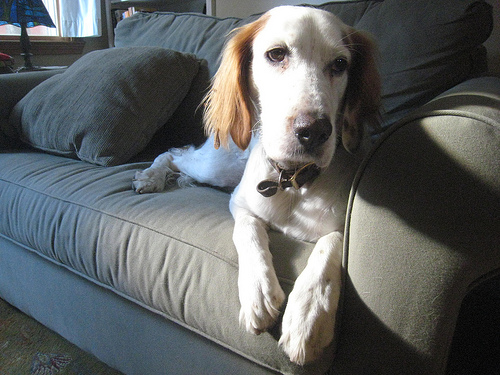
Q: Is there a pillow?
A: Yes, there is a pillow.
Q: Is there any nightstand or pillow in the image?
A: Yes, there is a pillow.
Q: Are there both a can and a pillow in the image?
A: No, there is a pillow but no cans.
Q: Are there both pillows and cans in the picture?
A: No, there is a pillow but no cans.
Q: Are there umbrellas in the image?
A: No, there are no umbrellas.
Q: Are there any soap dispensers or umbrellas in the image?
A: No, there are no umbrellas or soap dispensers.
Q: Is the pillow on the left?
A: Yes, the pillow is on the left of the image.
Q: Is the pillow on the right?
A: No, the pillow is on the left of the image.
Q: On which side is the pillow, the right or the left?
A: The pillow is on the left of the image.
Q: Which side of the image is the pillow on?
A: The pillow is on the left of the image.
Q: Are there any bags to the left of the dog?
A: No, there is a pillow to the left of the dog.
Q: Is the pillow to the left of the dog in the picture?
A: Yes, the pillow is to the left of the dog.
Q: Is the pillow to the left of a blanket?
A: No, the pillow is to the left of the dog.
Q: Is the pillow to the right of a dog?
A: No, the pillow is to the left of a dog.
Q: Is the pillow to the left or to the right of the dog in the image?
A: The pillow is to the left of the dog.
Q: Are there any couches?
A: Yes, there is a couch.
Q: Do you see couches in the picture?
A: Yes, there is a couch.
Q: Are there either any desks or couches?
A: Yes, there is a couch.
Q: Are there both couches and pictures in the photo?
A: No, there is a couch but no pictures.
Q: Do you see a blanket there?
A: No, there are no blankets.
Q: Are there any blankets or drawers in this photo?
A: No, there are no blankets or drawers.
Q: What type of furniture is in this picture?
A: The furniture is a couch.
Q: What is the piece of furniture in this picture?
A: The piece of furniture is a couch.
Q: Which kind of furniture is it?
A: The piece of furniture is a couch.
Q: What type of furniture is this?
A: This is a couch.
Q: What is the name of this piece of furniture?
A: This is a couch.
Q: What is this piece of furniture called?
A: This is a couch.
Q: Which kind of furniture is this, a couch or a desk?
A: This is a couch.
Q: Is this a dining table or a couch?
A: This is a couch.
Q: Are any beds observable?
A: No, there are no beds.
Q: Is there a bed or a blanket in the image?
A: No, there are no beds or blankets.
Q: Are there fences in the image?
A: No, there are no fences.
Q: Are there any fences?
A: No, there are no fences.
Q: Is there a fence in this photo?
A: No, there are no fences.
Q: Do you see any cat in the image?
A: No, there are no cats.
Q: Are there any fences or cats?
A: No, there are no cats or fences.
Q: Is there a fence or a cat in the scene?
A: No, there are no cats or fences.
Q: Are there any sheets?
A: No, there are no sheets.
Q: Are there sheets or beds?
A: No, there are no sheets or beds.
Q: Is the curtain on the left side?
A: Yes, the curtain is on the left of the image.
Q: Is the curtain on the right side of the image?
A: No, the curtain is on the left of the image.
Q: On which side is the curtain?
A: The curtain is on the left of the image.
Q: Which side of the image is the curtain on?
A: The curtain is on the left of the image.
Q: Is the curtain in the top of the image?
A: Yes, the curtain is in the top of the image.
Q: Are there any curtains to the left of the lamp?
A: No, the curtain is to the right of the lamp.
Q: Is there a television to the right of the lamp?
A: No, there is a curtain to the right of the lamp.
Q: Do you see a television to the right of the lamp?
A: No, there is a curtain to the right of the lamp.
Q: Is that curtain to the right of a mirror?
A: No, the curtain is to the right of the lamp.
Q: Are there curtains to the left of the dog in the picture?
A: Yes, there is a curtain to the left of the dog.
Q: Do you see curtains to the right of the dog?
A: No, the curtain is to the left of the dog.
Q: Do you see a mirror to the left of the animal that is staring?
A: No, there is a curtain to the left of the dog.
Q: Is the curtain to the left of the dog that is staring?
A: Yes, the curtain is to the left of the dog.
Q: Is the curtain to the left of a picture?
A: No, the curtain is to the left of the dog.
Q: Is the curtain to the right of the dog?
A: No, the curtain is to the left of the dog.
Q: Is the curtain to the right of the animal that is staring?
A: No, the curtain is to the left of the dog.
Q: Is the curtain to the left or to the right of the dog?
A: The curtain is to the left of the dog.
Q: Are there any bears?
A: No, there are no bears.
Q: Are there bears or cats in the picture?
A: No, there are no bears or cats.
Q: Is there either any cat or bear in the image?
A: No, there are no bears or cats.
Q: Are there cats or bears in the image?
A: No, there are no bears or cats.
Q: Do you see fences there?
A: No, there are no fences.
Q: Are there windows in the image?
A: Yes, there is a window.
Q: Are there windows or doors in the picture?
A: Yes, there is a window.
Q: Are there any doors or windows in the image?
A: Yes, there is a window.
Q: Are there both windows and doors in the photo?
A: No, there is a window but no doors.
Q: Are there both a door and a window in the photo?
A: No, there is a window but no doors.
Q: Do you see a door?
A: No, there are no doors.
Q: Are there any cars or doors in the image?
A: No, there are no doors or cars.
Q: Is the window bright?
A: Yes, the window is bright.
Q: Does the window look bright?
A: Yes, the window is bright.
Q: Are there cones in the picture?
A: No, there are no cones.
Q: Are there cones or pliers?
A: No, there are no cones or pliers.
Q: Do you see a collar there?
A: Yes, there is a collar.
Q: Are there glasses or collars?
A: Yes, there is a collar.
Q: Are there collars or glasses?
A: Yes, there is a collar.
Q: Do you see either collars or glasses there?
A: Yes, there is a collar.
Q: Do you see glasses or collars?
A: Yes, there is a collar.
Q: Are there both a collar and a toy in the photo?
A: No, there is a collar but no toys.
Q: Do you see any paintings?
A: No, there are no paintings.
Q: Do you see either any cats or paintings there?
A: No, there are no paintings or cats.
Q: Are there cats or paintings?
A: No, there are no paintings or cats.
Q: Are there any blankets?
A: No, there are no blankets.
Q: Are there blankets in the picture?
A: No, there are no blankets.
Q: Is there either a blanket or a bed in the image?
A: No, there are no blankets or beds.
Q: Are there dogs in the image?
A: Yes, there is a dog.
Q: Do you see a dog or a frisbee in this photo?
A: Yes, there is a dog.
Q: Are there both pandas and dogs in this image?
A: No, there is a dog but no pandas.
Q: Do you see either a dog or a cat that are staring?
A: Yes, the dog is staring.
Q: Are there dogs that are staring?
A: Yes, there is a dog that is staring.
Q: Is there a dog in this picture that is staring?
A: Yes, there is a dog that is staring.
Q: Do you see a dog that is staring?
A: Yes, there is a dog that is staring.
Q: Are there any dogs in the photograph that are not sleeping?
A: Yes, there is a dog that is staring.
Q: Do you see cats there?
A: No, there are no cats.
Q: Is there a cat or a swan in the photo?
A: No, there are no cats or swans.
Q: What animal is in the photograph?
A: The animal is a dog.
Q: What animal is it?
A: The animal is a dog.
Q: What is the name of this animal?
A: This is a dog.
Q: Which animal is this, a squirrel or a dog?
A: This is a dog.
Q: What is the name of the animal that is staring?
A: The animal is a dog.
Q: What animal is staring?
A: The animal is a dog.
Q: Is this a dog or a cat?
A: This is a dog.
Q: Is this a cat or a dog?
A: This is a dog.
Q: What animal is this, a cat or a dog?
A: This is a dog.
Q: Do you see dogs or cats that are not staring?
A: No, there is a dog but it is staring.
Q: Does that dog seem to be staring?
A: Yes, the dog is staring.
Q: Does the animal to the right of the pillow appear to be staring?
A: Yes, the dog is staring.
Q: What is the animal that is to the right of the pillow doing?
A: The dog is staring.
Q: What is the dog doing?
A: The dog is staring.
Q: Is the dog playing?
A: No, the dog is staring.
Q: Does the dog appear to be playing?
A: No, the dog is staring.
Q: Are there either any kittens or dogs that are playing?
A: No, there is a dog but it is staring.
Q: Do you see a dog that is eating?
A: No, there is a dog but it is staring.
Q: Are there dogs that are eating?
A: No, there is a dog but it is staring.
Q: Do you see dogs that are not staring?
A: No, there is a dog but it is staring.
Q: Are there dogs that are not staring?
A: No, there is a dog but it is staring.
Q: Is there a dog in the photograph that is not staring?
A: No, there is a dog but it is staring.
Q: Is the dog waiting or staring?
A: The dog is staring.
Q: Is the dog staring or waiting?
A: The dog is staring.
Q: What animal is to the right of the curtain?
A: The animal is a dog.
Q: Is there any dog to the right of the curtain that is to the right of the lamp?
A: Yes, there is a dog to the right of the curtain.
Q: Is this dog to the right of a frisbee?
A: No, the dog is to the right of the curtain.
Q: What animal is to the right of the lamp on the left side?
A: The animal is a dog.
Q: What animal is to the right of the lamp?
A: The animal is a dog.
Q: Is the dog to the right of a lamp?
A: Yes, the dog is to the right of a lamp.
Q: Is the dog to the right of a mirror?
A: No, the dog is to the right of a lamp.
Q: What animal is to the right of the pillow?
A: The animal is a dog.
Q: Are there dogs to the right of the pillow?
A: Yes, there is a dog to the right of the pillow.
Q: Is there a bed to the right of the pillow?
A: No, there is a dog to the right of the pillow.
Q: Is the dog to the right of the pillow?
A: Yes, the dog is to the right of the pillow.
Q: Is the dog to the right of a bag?
A: No, the dog is to the right of the pillow.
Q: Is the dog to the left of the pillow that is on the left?
A: No, the dog is to the right of the pillow.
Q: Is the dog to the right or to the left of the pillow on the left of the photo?
A: The dog is to the right of the pillow.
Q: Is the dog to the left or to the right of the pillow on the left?
A: The dog is to the right of the pillow.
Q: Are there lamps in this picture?
A: Yes, there is a lamp.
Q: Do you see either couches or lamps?
A: Yes, there is a lamp.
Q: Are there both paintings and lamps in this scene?
A: No, there is a lamp but no paintings.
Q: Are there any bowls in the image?
A: No, there are no bowls.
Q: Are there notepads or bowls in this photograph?
A: No, there are no bowls or notepads.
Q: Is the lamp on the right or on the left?
A: The lamp is on the left of the image.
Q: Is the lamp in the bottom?
A: No, the lamp is in the top of the image.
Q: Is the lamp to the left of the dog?
A: Yes, the lamp is to the left of the dog.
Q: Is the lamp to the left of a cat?
A: No, the lamp is to the left of the dog.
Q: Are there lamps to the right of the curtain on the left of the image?
A: No, the lamp is to the left of the curtain.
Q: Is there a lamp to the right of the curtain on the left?
A: No, the lamp is to the left of the curtain.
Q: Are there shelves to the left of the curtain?
A: No, there is a lamp to the left of the curtain.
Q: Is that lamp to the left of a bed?
A: No, the lamp is to the left of the curtain.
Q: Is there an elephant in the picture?
A: No, there are no elephants.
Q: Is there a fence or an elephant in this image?
A: No, there are no elephants or fences.